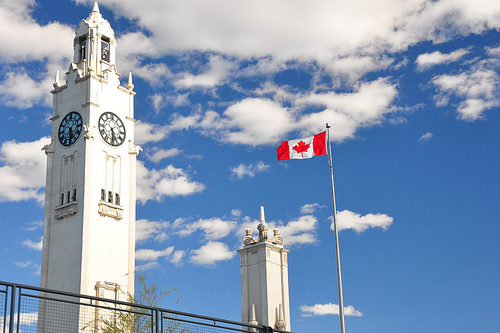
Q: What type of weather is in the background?
A: It is sunny.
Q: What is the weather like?
A: It is sunny.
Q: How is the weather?
A: It is sunny.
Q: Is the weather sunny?
A: Yes, it is sunny.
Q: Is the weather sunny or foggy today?
A: It is sunny.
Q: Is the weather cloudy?
A: No, it is sunny.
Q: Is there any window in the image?
A: Yes, there are windows.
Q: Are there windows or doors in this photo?
A: Yes, there are windows.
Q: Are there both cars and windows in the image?
A: No, there are windows but no cars.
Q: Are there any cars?
A: No, there are no cars.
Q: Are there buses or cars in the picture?
A: No, there are no cars or buses.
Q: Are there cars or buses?
A: No, there are no cars or buses.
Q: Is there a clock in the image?
A: Yes, there is a clock.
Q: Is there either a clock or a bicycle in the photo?
A: Yes, there is a clock.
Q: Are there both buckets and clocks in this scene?
A: No, there is a clock but no buckets.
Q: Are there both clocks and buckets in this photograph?
A: No, there is a clock but no buckets.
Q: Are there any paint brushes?
A: No, there are no paint brushes.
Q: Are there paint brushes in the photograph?
A: No, there are no paint brushes.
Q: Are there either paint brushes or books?
A: No, there are no paint brushes or books.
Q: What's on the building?
A: The clock is on the building.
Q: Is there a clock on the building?
A: Yes, there is a clock on the building.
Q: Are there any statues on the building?
A: No, there is a clock on the building.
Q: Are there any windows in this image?
A: Yes, there is a window.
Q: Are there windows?
A: Yes, there is a window.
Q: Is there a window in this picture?
A: Yes, there is a window.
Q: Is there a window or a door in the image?
A: Yes, there is a window.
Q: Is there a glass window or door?
A: Yes, there is a glass window.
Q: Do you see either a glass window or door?
A: Yes, there is a glass window.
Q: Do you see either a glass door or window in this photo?
A: Yes, there is a glass window.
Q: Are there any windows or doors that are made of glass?
A: Yes, the window is made of glass.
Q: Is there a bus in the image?
A: No, there are no buses.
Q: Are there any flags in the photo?
A: Yes, there is a flag.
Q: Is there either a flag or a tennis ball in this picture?
A: Yes, there is a flag.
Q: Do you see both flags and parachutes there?
A: No, there is a flag but no parachutes.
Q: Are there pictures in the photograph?
A: No, there are no pictures.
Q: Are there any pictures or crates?
A: No, there are no pictures or crates.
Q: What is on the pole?
A: The flag is on the pole.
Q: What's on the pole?
A: The flag is on the pole.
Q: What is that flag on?
A: The flag is on the pole.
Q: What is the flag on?
A: The flag is on the pole.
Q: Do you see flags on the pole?
A: Yes, there is a flag on the pole.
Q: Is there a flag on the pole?
A: Yes, there is a flag on the pole.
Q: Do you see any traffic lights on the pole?
A: No, there is a flag on the pole.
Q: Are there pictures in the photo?
A: No, there are no pictures.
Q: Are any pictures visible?
A: No, there are no pictures.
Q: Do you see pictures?
A: No, there are no pictures.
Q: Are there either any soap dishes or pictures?
A: No, there are no pictures or soap dishes.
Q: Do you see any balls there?
A: No, there are no balls.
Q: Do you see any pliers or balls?
A: No, there are no balls or pliers.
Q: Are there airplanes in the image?
A: No, there are no airplanes.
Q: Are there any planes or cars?
A: No, there are no planes or cars.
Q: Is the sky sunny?
A: Yes, the sky is sunny.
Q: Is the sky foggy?
A: No, the sky is sunny.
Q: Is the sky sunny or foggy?
A: The sky is sunny.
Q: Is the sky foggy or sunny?
A: The sky is sunny.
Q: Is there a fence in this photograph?
A: Yes, there is a fence.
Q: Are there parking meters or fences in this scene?
A: Yes, there is a fence.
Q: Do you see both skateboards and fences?
A: No, there is a fence but no skateboards.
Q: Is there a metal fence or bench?
A: Yes, there is a metal fence.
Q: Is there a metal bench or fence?
A: Yes, there is a metal fence.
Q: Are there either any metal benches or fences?
A: Yes, there is a metal fence.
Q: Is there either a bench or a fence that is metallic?
A: Yes, the fence is metallic.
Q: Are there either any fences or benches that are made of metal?
A: Yes, the fence is made of metal.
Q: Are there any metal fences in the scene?
A: Yes, there is a metal fence.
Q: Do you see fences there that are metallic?
A: Yes, there is a fence that is metallic.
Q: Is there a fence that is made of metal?
A: Yes, there is a fence that is made of metal.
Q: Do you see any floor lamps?
A: No, there are no floor lamps.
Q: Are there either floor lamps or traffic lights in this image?
A: No, there are no floor lamps or traffic lights.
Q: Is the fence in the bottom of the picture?
A: Yes, the fence is in the bottom of the image.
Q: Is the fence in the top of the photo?
A: No, the fence is in the bottom of the image.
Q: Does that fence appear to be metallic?
A: Yes, the fence is metallic.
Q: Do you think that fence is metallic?
A: Yes, the fence is metallic.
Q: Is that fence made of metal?
A: Yes, the fence is made of metal.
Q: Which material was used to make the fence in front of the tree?
A: The fence is made of metal.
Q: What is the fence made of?
A: The fence is made of metal.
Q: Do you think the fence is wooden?
A: No, the fence is metallic.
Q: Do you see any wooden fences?
A: No, there is a fence but it is metallic.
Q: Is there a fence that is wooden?
A: No, there is a fence but it is metallic.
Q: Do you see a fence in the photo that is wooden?
A: No, there is a fence but it is metallic.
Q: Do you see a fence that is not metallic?
A: No, there is a fence but it is metallic.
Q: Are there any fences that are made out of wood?
A: No, there is a fence but it is made of metal.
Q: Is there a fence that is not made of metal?
A: No, there is a fence but it is made of metal.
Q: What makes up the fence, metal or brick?
A: The fence is made of metal.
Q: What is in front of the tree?
A: The fence is in front of the tree.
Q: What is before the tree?
A: The fence is in front of the tree.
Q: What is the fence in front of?
A: The fence is in front of the tree.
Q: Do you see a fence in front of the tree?
A: Yes, there is a fence in front of the tree.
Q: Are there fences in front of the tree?
A: Yes, there is a fence in front of the tree.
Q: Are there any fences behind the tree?
A: No, the fence is in front of the tree.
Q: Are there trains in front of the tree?
A: No, there is a fence in front of the tree.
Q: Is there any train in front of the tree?
A: No, there is a fence in front of the tree.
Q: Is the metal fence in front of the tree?
A: Yes, the fence is in front of the tree.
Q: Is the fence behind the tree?
A: No, the fence is in front of the tree.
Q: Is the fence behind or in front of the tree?
A: The fence is in front of the tree.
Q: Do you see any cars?
A: No, there are no cars.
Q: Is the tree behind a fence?
A: Yes, the tree is behind a fence.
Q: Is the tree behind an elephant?
A: No, the tree is behind a fence.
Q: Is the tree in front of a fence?
A: No, the tree is behind a fence.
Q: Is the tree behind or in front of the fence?
A: The tree is behind the fence.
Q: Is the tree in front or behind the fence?
A: The tree is behind the fence.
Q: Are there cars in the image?
A: No, there are no cars.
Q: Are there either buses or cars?
A: No, there are no cars or buses.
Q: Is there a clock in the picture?
A: Yes, there is a clock.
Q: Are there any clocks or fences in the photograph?
A: Yes, there is a clock.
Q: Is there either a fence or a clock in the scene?
A: Yes, there is a clock.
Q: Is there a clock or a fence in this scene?
A: Yes, there is a clock.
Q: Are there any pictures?
A: No, there are no pictures.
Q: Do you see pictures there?
A: No, there are no pictures.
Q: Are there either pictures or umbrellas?
A: No, there are no pictures or umbrellas.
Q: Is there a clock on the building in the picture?
A: Yes, there is a clock on the building.